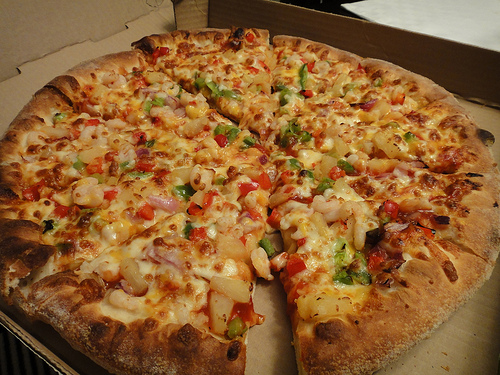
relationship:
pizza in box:
[7, 27, 497, 371] [2, 8, 487, 356]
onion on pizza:
[82, 179, 147, 286] [7, 27, 497, 371]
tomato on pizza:
[201, 167, 281, 224] [199, 60, 448, 234]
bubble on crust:
[312, 319, 348, 344] [294, 238, 489, 373]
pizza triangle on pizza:
[271, 170, 493, 375] [7, 27, 497, 371]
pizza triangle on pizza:
[271, 170, 498, 262] [7, 27, 497, 371]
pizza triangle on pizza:
[273, 95, 498, 174] [7, 27, 497, 371]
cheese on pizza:
[146, 254, 220, 325] [7, 27, 497, 371]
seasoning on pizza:
[92, 47, 423, 311] [7, 27, 497, 371]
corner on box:
[174, 2, 211, 30] [0, 0, 500, 375]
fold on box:
[2, 5, 198, 86] [2, 8, 487, 356]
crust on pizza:
[0, 214, 55, 286] [3, 237, 62, 304]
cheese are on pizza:
[146, 254, 220, 325] [7, 27, 497, 371]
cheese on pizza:
[327, 188, 354, 223] [7, 27, 497, 371]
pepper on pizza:
[319, 237, 384, 290] [7, 27, 497, 371]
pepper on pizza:
[294, 62, 320, 90] [7, 27, 497, 371]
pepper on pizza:
[212, 117, 262, 144] [7, 27, 497, 371]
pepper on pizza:
[170, 176, 200, 204] [7, 27, 497, 371]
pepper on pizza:
[334, 157, 375, 177] [7, 27, 497, 371]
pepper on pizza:
[249, 230, 285, 255] [7, 27, 497, 371]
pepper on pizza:
[219, 311, 256, 338] [7, 27, 497, 371]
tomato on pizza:
[132, 200, 169, 225] [7, 27, 497, 371]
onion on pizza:
[5, 27, 497, 373] [7, 27, 497, 371]